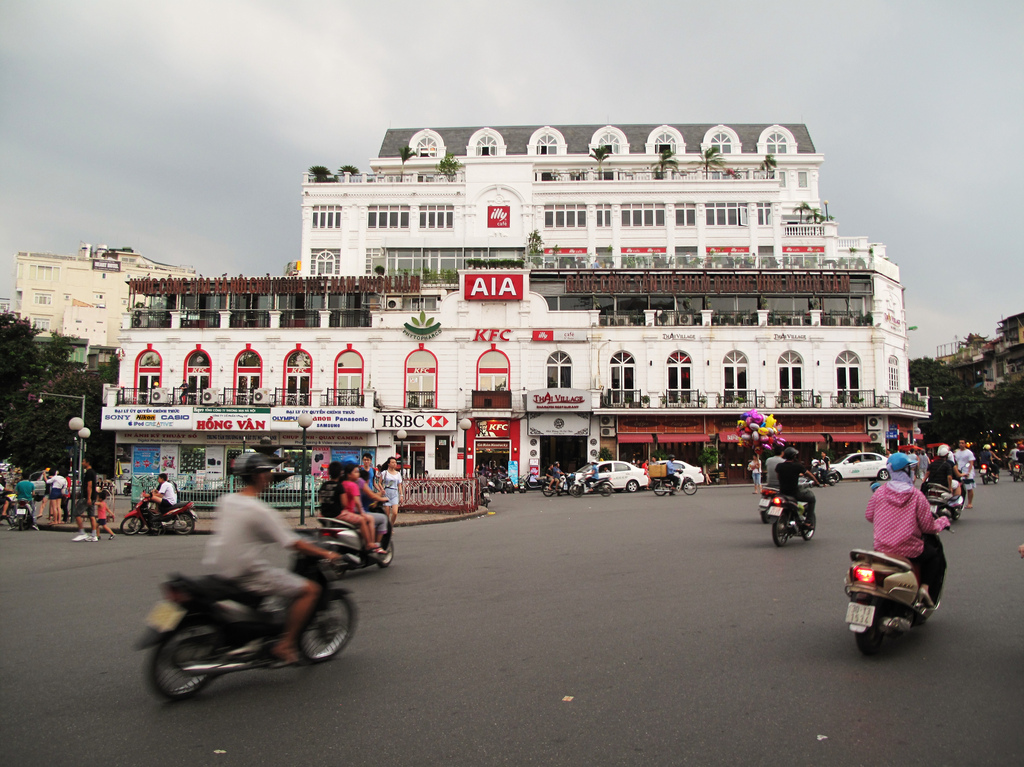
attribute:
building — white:
[99, 134, 913, 468]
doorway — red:
[466, 419, 521, 483]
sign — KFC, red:
[475, 410, 515, 441]